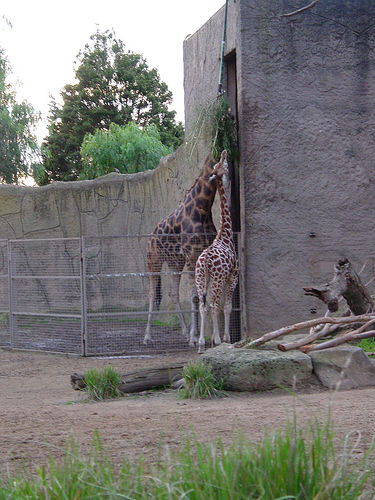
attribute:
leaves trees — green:
[53, 94, 172, 164]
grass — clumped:
[159, 349, 231, 404]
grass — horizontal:
[88, 337, 134, 409]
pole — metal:
[217, 14, 228, 92]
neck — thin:
[216, 182, 234, 242]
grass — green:
[5, 426, 361, 498]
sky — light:
[1, 3, 254, 201]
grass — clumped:
[183, 363, 229, 393]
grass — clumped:
[82, 366, 121, 397]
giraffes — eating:
[143, 106, 231, 343]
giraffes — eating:
[188, 147, 239, 353]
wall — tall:
[240, 2, 373, 336]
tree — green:
[79, 119, 155, 177]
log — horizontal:
[68, 357, 192, 393]